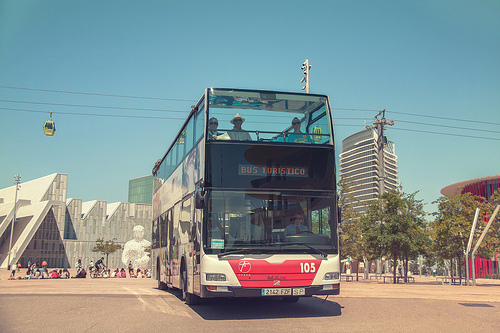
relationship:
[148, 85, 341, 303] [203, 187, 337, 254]
bus has window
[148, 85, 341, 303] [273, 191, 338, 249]
bus has window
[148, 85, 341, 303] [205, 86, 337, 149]
bus has window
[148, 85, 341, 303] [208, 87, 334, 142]
bus has window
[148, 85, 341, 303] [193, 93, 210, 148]
bus has window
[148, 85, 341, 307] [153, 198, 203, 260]
bus has window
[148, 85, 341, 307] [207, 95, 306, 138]
bus has window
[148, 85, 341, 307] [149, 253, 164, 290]
bus has tire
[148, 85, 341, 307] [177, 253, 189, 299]
bus has tire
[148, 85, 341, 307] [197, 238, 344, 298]
bus has bumper